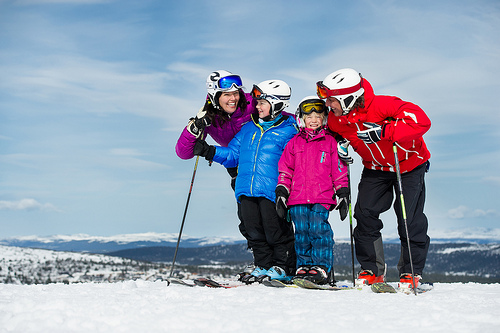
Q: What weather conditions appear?
A: It is cloudy.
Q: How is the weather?
A: It is cloudy.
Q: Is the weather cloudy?
A: Yes, it is cloudy.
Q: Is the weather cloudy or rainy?
A: It is cloudy.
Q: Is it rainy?
A: No, it is cloudy.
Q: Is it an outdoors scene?
A: Yes, it is outdoors.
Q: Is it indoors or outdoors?
A: It is outdoors.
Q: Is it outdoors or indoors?
A: It is outdoors.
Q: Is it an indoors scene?
A: No, it is outdoors.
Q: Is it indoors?
A: No, it is outdoors.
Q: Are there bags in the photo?
A: No, there are no bags.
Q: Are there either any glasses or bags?
A: No, there are no bags or glasses.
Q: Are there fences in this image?
A: No, there are no fences.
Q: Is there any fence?
A: No, there are no fences.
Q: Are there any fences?
A: No, there are no fences.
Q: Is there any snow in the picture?
A: Yes, there is snow.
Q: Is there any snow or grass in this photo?
A: Yes, there is snow.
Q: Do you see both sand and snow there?
A: No, there is snow but no sand.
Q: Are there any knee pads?
A: No, there are no knee pads.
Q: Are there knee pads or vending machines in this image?
A: No, there are no knee pads or vending machines.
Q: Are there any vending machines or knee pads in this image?
A: No, there are no knee pads or vending machines.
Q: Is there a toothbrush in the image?
A: No, there are no toothbrushes.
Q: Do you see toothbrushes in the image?
A: No, there are no toothbrushes.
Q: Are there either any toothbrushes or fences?
A: No, there are no toothbrushes or fences.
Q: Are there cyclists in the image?
A: No, there are no cyclists.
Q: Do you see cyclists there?
A: No, there are no cyclists.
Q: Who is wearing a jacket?
A: The boy is wearing a jacket.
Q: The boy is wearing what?
A: The boy is wearing a jacket.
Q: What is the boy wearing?
A: The boy is wearing a jacket.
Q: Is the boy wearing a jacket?
A: Yes, the boy is wearing a jacket.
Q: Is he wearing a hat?
A: No, the boy is wearing a jacket.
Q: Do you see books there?
A: No, there are no books.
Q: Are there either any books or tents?
A: No, there are no books or tents.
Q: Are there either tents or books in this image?
A: No, there are no books or tents.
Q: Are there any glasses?
A: No, there are no glasses.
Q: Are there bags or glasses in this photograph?
A: No, there are no glasses or bags.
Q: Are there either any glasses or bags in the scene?
A: No, there are no glasses or bags.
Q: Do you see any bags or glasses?
A: No, there are no glasses or bags.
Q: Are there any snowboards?
A: No, there are no snowboards.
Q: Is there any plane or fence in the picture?
A: No, there are no fences or airplanes.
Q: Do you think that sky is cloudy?
A: Yes, the sky is cloudy.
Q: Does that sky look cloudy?
A: Yes, the sky is cloudy.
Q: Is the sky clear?
A: No, the sky is cloudy.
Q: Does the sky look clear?
A: No, the sky is cloudy.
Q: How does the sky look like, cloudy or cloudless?
A: The sky is cloudy.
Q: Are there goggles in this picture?
A: Yes, there are goggles.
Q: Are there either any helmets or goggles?
A: Yes, there are goggles.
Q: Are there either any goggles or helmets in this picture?
A: Yes, there are goggles.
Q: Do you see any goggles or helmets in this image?
A: Yes, there are goggles.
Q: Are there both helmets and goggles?
A: Yes, there are both goggles and a helmet.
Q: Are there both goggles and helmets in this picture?
A: Yes, there are both goggles and a helmet.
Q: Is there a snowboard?
A: No, there are no snowboards.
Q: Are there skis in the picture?
A: Yes, there are skis.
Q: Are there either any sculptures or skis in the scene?
A: Yes, there are skis.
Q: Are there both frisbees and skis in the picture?
A: No, there are skis but no frisbees.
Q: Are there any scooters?
A: No, there are no scooters.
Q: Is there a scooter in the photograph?
A: No, there are no scooters.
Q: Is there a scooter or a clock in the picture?
A: No, there are no scooters or clocks.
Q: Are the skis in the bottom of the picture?
A: Yes, the skis are in the bottom of the image.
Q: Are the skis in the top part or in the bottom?
A: The skis are in the bottom of the image.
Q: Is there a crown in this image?
A: No, there are no crowns.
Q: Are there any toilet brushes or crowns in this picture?
A: No, there are no crowns or toilet brushes.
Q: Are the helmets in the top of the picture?
A: Yes, the helmets are in the top of the image.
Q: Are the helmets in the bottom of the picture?
A: No, the helmets are in the top of the image.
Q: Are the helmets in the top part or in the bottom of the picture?
A: The helmets are in the top of the image.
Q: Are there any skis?
A: Yes, there are skis.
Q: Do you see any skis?
A: Yes, there are skis.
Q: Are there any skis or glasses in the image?
A: Yes, there are skis.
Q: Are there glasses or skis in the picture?
A: Yes, there are skis.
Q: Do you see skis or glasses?
A: Yes, there are skis.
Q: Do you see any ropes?
A: No, there are no ropes.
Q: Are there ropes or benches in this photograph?
A: No, there are no ropes or benches.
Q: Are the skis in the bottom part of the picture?
A: Yes, the skis are in the bottom of the image.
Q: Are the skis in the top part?
A: No, the skis are in the bottom of the image.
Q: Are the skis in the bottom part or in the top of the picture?
A: The skis are in the bottom of the image.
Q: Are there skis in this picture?
A: Yes, there are skis.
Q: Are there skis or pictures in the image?
A: Yes, there are skis.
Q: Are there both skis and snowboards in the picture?
A: No, there are skis but no snowboards.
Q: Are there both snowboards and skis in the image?
A: No, there are skis but no snowboards.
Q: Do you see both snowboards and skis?
A: No, there are skis but no snowboards.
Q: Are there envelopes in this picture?
A: No, there are no envelopes.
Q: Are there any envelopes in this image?
A: No, there are no envelopes.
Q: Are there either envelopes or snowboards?
A: No, there are no envelopes or snowboards.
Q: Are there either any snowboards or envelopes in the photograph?
A: No, there are no envelopes or snowboards.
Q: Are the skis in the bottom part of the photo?
A: Yes, the skis are in the bottom of the image.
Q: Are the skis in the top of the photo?
A: No, the skis are in the bottom of the image.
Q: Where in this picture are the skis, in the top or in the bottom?
A: The skis are in the bottom of the image.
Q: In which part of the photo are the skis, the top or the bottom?
A: The skis are in the bottom of the image.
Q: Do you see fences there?
A: No, there are no fences.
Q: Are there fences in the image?
A: No, there are no fences.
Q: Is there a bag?
A: No, there are no bags.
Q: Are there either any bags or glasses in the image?
A: No, there are no bags or glasses.